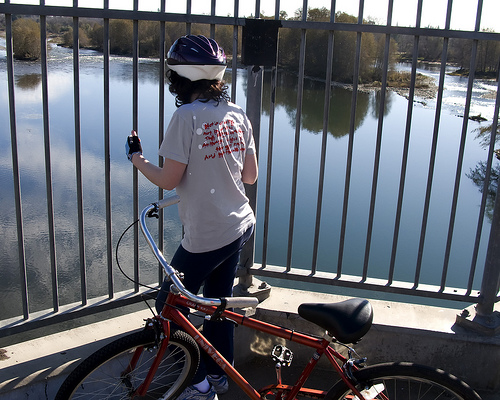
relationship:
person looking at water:
[126, 34, 258, 398] [0, 31, 499, 321]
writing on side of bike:
[188, 300, 228, 371] [54, 198, 482, 397]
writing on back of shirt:
[203, 113, 247, 160] [159, 98, 257, 253]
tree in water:
[10, 15, 53, 62] [0, 31, 499, 321]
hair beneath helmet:
[167, 69, 230, 108] [163, 34, 229, 83]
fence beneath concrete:
[2, 0, 500, 340] [2, 270, 499, 398]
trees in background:
[0, 1, 500, 105] [0, 0, 499, 320]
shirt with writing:
[159, 98, 257, 253] [203, 113, 247, 160]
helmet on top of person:
[163, 34, 229, 83] [126, 34, 258, 398]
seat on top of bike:
[299, 298, 374, 343] [54, 198, 482, 397]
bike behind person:
[54, 198, 482, 397] [126, 34, 258, 398]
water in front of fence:
[0, 31, 499, 321] [2, 0, 500, 340]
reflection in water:
[2, 52, 500, 126] [0, 31, 499, 321]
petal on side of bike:
[270, 341, 293, 368] [54, 198, 482, 397]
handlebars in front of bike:
[139, 193, 259, 306] [54, 198, 482, 397]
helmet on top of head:
[163, 34, 229, 83] [167, 34, 232, 108]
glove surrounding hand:
[124, 136, 144, 161] [126, 127, 145, 162]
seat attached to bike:
[299, 298, 374, 343] [54, 198, 482, 397]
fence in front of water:
[2, 0, 500, 340] [0, 31, 499, 321]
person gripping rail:
[126, 34, 258, 398] [133, 1, 142, 293]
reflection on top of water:
[2, 52, 500, 126] [0, 31, 499, 321]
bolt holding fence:
[452, 288, 460, 293] [2, 0, 500, 340]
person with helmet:
[126, 34, 258, 398] [163, 34, 229, 83]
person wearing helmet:
[126, 34, 258, 398] [163, 34, 229, 83]